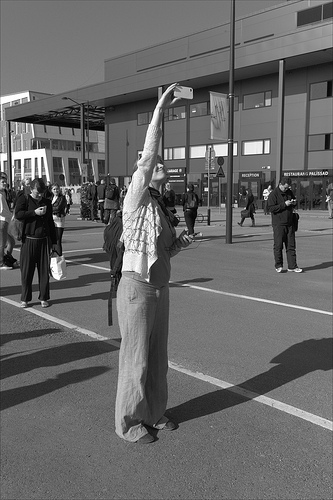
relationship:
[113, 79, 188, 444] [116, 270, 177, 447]
person wears pants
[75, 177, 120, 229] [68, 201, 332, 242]
people on road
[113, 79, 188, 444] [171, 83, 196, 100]
person holds phone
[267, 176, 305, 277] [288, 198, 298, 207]
man holds phone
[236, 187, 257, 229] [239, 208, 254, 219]
person wears bag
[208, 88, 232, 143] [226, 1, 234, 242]
banner on pole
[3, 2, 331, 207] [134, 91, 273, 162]
building has windows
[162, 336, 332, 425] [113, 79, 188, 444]
shadow of person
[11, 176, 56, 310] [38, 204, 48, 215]
woman using phone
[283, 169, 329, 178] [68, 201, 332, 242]
sign beside street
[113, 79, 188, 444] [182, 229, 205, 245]
person holds electronics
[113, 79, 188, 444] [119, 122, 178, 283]
person wears sweater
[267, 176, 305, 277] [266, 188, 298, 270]
man wearing clothes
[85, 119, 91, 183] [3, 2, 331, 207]
column behind building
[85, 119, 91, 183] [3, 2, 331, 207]
column in corner of building